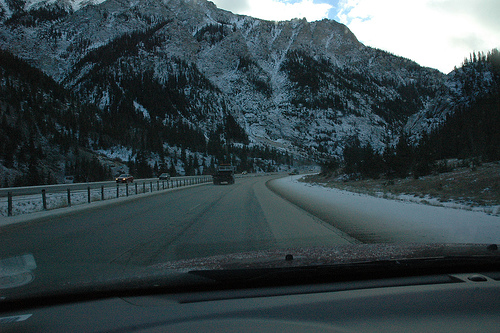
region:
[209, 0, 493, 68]
Clouds nearly completely cover the sky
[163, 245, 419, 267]
Snow on the hood of the car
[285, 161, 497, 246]
Snow on the side of the road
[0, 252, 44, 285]
Reflection in wind shield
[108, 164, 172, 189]
Two cars in the oncoming lane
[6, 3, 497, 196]
Ever green trees cover the mountains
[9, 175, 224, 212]
Divisions between lanes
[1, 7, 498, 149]
Snow covering the mountains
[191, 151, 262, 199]
a car on the road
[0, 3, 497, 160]
huge mountains all around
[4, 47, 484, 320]
a highway running through the mountains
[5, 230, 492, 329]
the front of a car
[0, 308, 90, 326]
a sticker on the dash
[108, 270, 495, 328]
the vent in the dash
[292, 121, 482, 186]
trees growing on the side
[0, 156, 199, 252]
a fence dividing the road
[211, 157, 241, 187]
a flatbed truck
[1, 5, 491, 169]
mountains covered with snow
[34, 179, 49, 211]
a wooden post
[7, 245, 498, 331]
a plastic dash board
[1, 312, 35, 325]
a barcode on the dash board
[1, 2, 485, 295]
a car wind shield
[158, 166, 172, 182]
a car coming in from traffic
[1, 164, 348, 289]
a highway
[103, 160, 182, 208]
two cars on the road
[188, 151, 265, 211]
a truck travelling on the road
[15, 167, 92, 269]
rails on a road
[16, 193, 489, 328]
the inside of a car windshield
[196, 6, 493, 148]
mountains with some snow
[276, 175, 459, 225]
the side of the road with snow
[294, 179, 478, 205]
snow covering the pavement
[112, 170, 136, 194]
car with headlights on in the distance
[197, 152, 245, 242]
back of a truck in the distance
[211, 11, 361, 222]
road curving to the right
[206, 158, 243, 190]
truck on road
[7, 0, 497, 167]
snow covered mountains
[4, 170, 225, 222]
fence bordering street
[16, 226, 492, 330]
hood of car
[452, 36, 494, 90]
tall trees on mountainside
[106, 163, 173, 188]
cars driving on highway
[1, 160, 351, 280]
bend in road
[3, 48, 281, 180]
trees on hill top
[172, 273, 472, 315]
vent opening on dashboard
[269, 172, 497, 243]
snow dusted on side of road